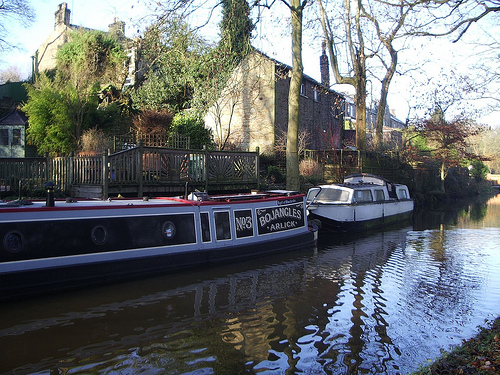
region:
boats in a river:
[23, 142, 471, 270]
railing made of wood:
[41, 124, 261, 205]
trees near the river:
[273, 6, 308, 208]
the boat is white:
[308, 164, 420, 237]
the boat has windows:
[310, 178, 401, 212]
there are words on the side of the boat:
[223, 198, 311, 242]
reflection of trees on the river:
[244, 261, 388, 360]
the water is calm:
[260, 268, 397, 348]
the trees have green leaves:
[60, 34, 255, 152]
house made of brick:
[203, 37, 354, 164]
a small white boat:
[306, 175, 412, 224]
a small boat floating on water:
[293, 168, 424, 238]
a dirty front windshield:
[308, 186, 348, 202]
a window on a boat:
[352, 189, 377, 206]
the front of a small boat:
[301, 183, 352, 227]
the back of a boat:
[386, 182, 416, 224]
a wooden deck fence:
[1, 155, 263, 187]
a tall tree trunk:
[283, 69, 303, 196]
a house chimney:
[53, 3, 71, 25]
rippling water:
[1, 200, 499, 372]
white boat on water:
[287, 163, 434, 238]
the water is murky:
[159, 302, 320, 363]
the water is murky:
[268, 253, 378, 357]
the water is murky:
[321, 290, 438, 356]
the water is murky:
[242, 282, 367, 335]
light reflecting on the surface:
[339, 287, 421, 336]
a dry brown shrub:
[295, 152, 317, 179]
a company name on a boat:
[256, 202, 309, 234]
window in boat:
[354, 186, 401, 202]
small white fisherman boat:
[309, 175, 419, 228]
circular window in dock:
[87, 217, 125, 252]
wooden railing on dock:
[131, 148, 249, 193]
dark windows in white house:
[0, 124, 27, 152]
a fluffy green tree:
[29, 74, 91, 148]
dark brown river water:
[146, 251, 454, 359]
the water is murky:
[120, 270, 234, 353]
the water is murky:
[319, 253, 439, 311]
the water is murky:
[362, 228, 468, 303]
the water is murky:
[182, 272, 348, 349]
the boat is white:
[273, 150, 440, 273]